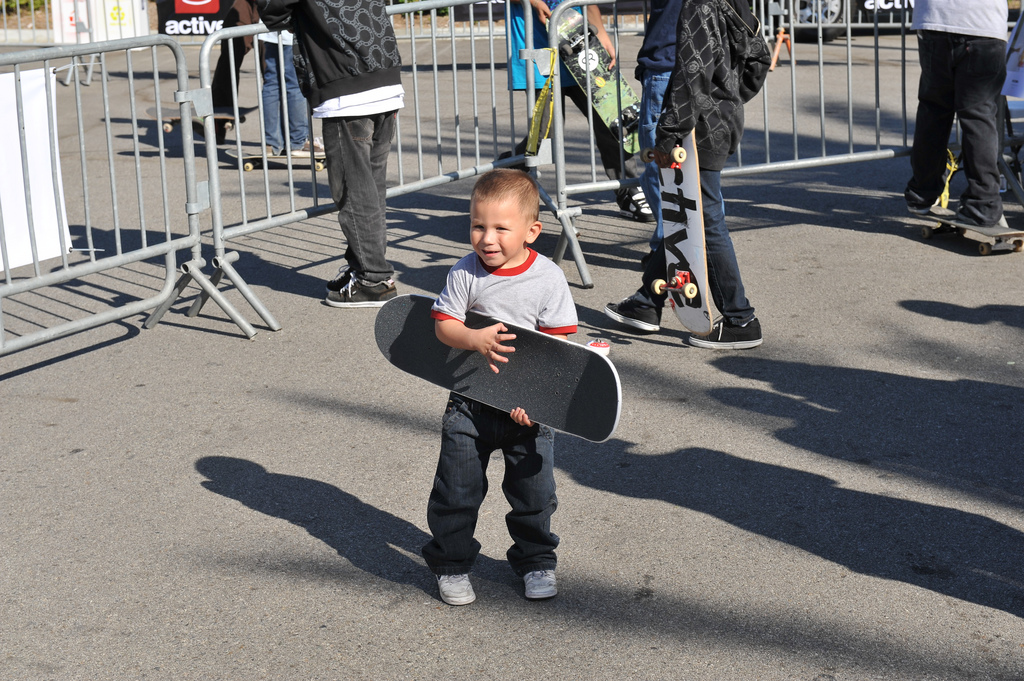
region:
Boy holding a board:
[368, 282, 625, 460]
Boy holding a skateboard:
[364, 273, 622, 450]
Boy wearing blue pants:
[416, 371, 587, 580]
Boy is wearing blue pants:
[416, 374, 584, 575]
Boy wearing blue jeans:
[422, 355, 572, 578]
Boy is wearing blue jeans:
[413, 377, 579, 578]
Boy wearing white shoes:
[418, 539, 562, 609]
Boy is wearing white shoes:
[415, 542, 584, 610]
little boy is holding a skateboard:
[356, 162, 626, 605]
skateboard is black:
[367, 279, 631, 470]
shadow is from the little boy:
[192, 447, 521, 607]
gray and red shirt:
[438, 238, 582, 375]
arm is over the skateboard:
[425, 308, 521, 373]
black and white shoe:
[604, 269, 675, 340]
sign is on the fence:
[2, 57, 94, 292]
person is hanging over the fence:
[244, 4, 423, 303]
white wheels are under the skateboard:
[646, 272, 703, 304]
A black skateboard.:
[371, 285, 627, 448]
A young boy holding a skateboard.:
[374, 176, 606, 616]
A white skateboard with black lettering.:
[640, 66, 720, 341]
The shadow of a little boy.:
[178, 436, 518, 604]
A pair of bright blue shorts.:
[506, 15, 542, 88]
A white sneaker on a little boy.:
[413, 557, 480, 603]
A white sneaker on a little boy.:
[510, 559, 561, 605]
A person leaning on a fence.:
[282, 0, 407, 304]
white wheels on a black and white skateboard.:
[650, 268, 696, 303]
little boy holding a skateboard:
[371, 161, 635, 604]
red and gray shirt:
[434, 238, 580, 338]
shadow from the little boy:
[192, 449, 524, 606]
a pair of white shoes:
[429, 570, 563, 600]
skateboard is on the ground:
[903, 200, 1022, 255]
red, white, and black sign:
[156, 1, 240, 40]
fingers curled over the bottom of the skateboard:
[510, 403, 536, 426]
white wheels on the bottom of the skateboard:
[646, 281, 714, 305]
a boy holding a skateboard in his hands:
[377, 169, 618, 609]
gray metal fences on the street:
[0, 2, 1015, 666]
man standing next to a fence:
[250, 4, 410, 308]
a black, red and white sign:
[155, 2, 232, 35]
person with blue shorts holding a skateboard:
[506, 0, 643, 187]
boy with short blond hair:
[424, 169, 581, 606]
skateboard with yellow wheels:
[640, 126, 716, 333]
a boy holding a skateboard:
[361, 183, 676, 572]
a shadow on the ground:
[238, 458, 412, 608]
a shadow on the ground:
[623, 413, 944, 638]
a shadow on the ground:
[735, 358, 928, 535]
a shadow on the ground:
[871, 265, 1008, 341]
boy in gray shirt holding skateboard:
[375, 170, 629, 619]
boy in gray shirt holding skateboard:
[366, 168, 645, 618]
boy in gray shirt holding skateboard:
[353, 165, 655, 625]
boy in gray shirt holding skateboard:
[346, 162, 657, 612]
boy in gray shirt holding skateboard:
[366, 171, 651, 609]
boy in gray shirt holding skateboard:
[357, 164, 649, 610]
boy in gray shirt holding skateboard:
[363, 160, 664, 609]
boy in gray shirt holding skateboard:
[357, 170, 643, 624]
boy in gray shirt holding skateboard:
[346, 162, 638, 608]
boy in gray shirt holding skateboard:
[353, 165, 663, 614]